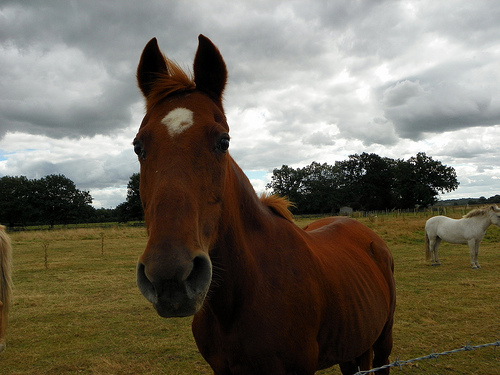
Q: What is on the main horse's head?
A: A spot.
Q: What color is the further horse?
A: White.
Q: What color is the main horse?
A: Brown.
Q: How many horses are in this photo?
A: Two.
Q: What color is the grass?
A: Green.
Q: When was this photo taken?
A: Outside, on a cloudy day.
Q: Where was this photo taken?
A: On a ranch.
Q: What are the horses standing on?
A: Grass.